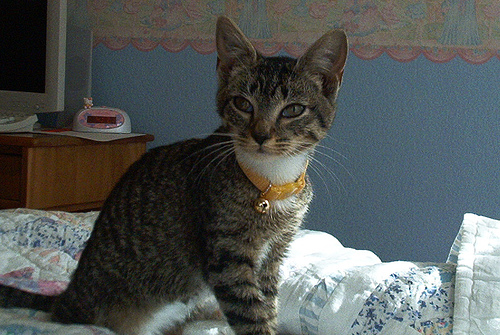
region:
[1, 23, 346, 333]
black white and brown cat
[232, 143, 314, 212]
orange collar with bells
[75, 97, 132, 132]
pink hello kitty digital clock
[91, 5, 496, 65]
pink blue and white wall painting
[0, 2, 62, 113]
early 2000s desktop computer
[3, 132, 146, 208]
brown wooden desk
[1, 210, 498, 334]
blue white and pink comforter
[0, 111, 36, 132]
white mechanical keyboard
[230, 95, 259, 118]
blue eyes on cat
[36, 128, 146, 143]
white paper on desk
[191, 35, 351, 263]
Cat with a bell.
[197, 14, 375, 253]
Cat with a collar.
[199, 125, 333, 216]
Yellow collar with a bell.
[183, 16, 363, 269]
Yellow collar on the cat.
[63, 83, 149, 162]
Clock on the nightstand.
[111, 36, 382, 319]
Striped cat on the bed.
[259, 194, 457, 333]
Quilt on the bed.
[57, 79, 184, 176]
Pink and white clock.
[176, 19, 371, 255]
Cat with whiskers.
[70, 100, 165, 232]
nightstand with a clock on it.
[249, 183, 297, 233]
Gold bell on cat's collar.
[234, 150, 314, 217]
Cat wearing yellow collar.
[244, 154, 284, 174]
Cat has white neck.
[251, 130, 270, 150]
End of cat's nose is black.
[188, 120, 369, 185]
Cat has white whiskers.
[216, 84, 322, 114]
Cat has green eyes.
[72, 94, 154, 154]
White hello kitty clock on table.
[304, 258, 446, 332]
White and blue blanket on bed.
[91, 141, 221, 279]
Cat has stripes on fur.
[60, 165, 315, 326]
Cat is sitting on bed.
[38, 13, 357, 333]
cat wearing a bell on a bed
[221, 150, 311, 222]
orange collar with a bell on a cat's neck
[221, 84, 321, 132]
eyes on a cat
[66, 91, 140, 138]
clock radio on a table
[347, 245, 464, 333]
blue pattern on a bed sheet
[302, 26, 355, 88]
grey striped ear on cat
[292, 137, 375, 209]
whiskers on a grey striped cat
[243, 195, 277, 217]
bell on a cat's collar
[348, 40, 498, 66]
lace on the bottom of a curtain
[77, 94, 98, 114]
hello kitty figure on top of radio clock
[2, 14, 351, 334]
a small tabby cat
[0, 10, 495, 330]
a cat on a quilt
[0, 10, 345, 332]
a cat wearing a yellow collar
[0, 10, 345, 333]
a cat wearing a collar with a bell on it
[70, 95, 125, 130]
a clock with a cat figurine on it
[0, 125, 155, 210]
the table with the clock on it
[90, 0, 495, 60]
a picture on the wall with a scalloped edging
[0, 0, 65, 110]
a white frame to the left of the cat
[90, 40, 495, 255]
blue area behind the cat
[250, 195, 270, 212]
the bell on the cat collar